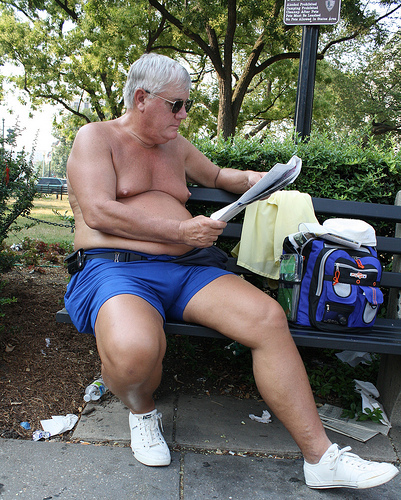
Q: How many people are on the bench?
A: 1.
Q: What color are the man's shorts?
A: Blue.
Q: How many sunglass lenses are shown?
A: 2.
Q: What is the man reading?
A: Newspaper.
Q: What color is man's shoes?
A: White.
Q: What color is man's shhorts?
A: Blue.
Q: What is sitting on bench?
A: Carry on bag.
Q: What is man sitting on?
A: Bench.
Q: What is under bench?
A: Trash.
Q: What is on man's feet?
A: White shoes.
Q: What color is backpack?
A: Blue.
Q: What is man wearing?
A: Blue shorts.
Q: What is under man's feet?
A: Concrete ground.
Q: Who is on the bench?
A: Shirtless man.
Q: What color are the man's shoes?
A: White.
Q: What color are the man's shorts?
A: Blue.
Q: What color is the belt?
A: Black.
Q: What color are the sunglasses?
A: Silver.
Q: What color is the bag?
A: Blue.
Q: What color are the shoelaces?
A: White.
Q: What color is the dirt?
A: Brown.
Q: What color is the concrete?
A: Gray.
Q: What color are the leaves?
A: Green.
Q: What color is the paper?
A: White.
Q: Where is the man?
A: Sitting on a bench.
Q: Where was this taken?
A: In a park.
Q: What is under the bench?
A: Trash.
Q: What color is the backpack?
A: Black, white and blue.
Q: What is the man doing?
A: Reading.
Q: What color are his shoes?
A: White.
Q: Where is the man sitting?
A: In the park.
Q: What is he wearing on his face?
A: Sunglasses.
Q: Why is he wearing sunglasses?
A: The sun is bright.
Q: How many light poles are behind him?
A: One.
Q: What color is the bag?
A: Blue.